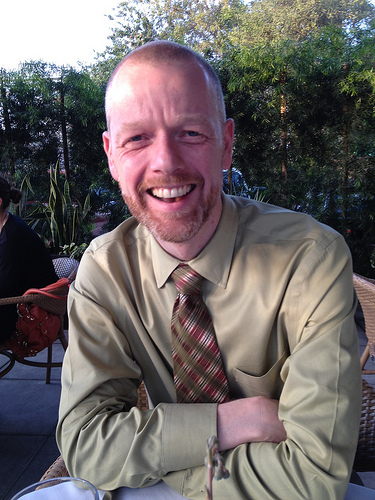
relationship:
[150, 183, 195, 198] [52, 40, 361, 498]
teeth on a man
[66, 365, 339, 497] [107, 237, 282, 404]
arms over chest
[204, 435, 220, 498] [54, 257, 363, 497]
rope near arms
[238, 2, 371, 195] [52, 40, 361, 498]
trees behind a man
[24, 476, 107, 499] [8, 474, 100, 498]
napkin near glass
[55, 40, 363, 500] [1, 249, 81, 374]
man sitting in chair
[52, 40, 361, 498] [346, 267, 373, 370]
man sitting in chair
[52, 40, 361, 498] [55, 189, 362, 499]
man wearing dress shirt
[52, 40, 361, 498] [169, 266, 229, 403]
man wearing tie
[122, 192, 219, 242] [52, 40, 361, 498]
beard on a man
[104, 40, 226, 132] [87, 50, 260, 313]
hair on man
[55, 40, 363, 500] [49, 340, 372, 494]
man has arms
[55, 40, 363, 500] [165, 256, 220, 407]
man wears tie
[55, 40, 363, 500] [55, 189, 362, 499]
man wears dress shirt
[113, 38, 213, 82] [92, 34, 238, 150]
hairline on head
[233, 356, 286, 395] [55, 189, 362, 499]
pocket of dress shirt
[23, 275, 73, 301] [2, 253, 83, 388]
bag on chair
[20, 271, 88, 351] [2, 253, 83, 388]
back of chair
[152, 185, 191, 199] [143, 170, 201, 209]
teeth in mouth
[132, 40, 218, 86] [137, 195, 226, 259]
hair on chin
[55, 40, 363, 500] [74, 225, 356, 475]
man in shirt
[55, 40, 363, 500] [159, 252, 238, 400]
man in tie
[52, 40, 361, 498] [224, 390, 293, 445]
man has hand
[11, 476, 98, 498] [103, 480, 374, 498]
glass rim on table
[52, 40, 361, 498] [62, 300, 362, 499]
man has arms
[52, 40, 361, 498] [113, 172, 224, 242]
man has beard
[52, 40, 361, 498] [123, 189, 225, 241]
man has beard